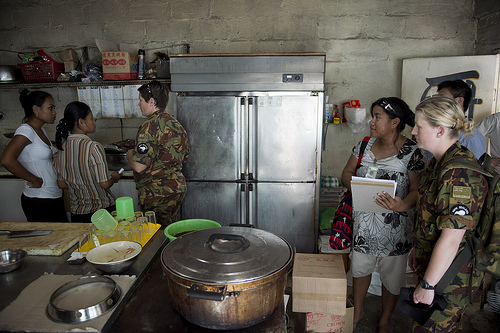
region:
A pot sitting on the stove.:
[159, 219, 296, 330]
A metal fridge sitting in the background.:
[154, 45, 327, 217]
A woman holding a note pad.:
[325, 75, 420, 326]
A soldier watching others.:
[382, 94, 497, 330]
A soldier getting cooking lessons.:
[15, 67, 197, 229]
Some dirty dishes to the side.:
[5, 189, 156, 286]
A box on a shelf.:
[83, 27, 140, 75]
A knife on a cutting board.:
[6, 211, 72, 260]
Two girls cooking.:
[0, 57, 132, 218]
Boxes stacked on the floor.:
[278, 236, 364, 331]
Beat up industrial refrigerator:
[167, 52, 324, 256]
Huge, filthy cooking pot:
[160, 224, 293, 330]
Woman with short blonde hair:
[409, 95, 492, 332]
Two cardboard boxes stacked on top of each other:
[289, 250, 356, 332]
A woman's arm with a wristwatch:
[409, 225, 466, 309]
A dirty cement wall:
[0, 0, 499, 176]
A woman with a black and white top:
[339, 95, 419, 330]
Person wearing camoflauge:
[122, 78, 193, 219]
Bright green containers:
[90, 192, 223, 249]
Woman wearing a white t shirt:
[1, 87, 63, 218]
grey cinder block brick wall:
[328, 12, 394, 89]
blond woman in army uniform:
[406, 96, 488, 331]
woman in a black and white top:
[326, 92, 420, 322]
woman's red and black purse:
[322, 175, 362, 256]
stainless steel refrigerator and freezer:
[167, 54, 332, 242]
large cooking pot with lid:
[157, 224, 309, 324]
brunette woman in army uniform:
[118, 76, 199, 216]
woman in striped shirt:
[53, 99, 117, 219]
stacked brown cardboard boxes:
[285, 244, 363, 331]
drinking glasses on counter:
[86, 190, 162, 240]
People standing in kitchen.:
[326, 78, 498, 328]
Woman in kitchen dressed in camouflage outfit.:
[411, 99, 493, 331]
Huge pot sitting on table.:
[159, 225, 296, 332]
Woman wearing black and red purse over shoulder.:
[326, 134, 373, 254]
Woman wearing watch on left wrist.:
[416, 271, 440, 293]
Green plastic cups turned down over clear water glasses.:
[86, 193, 141, 234]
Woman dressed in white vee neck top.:
[11, 123, 60, 201]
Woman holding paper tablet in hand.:
[347, 171, 407, 221]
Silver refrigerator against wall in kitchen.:
[174, 92, 329, 256]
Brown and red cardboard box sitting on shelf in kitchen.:
[95, 35, 142, 82]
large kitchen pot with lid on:
[155, 223, 302, 330]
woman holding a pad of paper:
[323, 86, 420, 324]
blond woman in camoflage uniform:
[402, 92, 497, 330]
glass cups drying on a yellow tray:
[79, 191, 166, 260]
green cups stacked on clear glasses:
[85, 190, 160, 248]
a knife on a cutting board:
[2, 211, 92, 262]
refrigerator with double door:
[162, 45, 336, 260]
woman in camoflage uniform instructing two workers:
[3, 73, 195, 223]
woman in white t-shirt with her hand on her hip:
[3, 84, 71, 224]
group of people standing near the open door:
[310, 46, 497, 331]